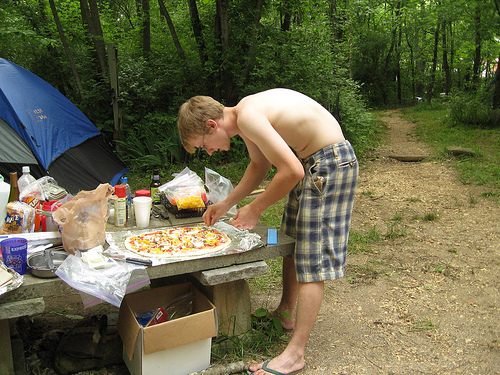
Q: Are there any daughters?
A: No, there are no daughters.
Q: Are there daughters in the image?
A: No, there are no daughters.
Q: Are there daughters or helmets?
A: No, there are no daughters or helmets.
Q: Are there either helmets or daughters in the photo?
A: No, there are no daughters or helmets.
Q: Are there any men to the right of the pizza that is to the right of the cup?
A: Yes, there is a man to the right of the pizza.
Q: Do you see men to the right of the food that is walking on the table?
A: Yes, there is a man to the right of the pizza.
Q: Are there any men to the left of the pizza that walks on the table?
A: No, the man is to the right of the pizza.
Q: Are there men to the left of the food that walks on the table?
A: No, the man is to the right of the pizza.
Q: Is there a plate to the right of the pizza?
A: No, there is a man to the right of the pizza.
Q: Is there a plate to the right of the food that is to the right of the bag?
A: No, there is a man to the right of the pizza.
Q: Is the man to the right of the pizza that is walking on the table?
A: Yes, the man is to the right of the pizza.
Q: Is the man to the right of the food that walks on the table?
A: Yes, the man is to the right of the pizza.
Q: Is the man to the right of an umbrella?
A: No, the man is to the right of the pizza.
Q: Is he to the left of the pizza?
A: No, the man is to the right of the pizza.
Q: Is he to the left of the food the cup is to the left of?
A: No, the man is to the right of the pizza.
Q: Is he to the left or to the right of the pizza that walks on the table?
A: The man is to the right of the pizza.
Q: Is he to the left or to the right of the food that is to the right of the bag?
A: The man is to the right of the pizza.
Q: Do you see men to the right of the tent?
A: Yes, there is a man to the right of the tent.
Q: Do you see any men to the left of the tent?
A: No, the man is to the right of the tent.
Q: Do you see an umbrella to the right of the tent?
A: No, there is a man to the right of the tent.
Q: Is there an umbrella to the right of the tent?
A: No, there is a man to the right of the tent.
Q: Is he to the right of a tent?
A: Yes, the man is to the right of a tent.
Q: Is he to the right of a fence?
A: No, the man is to the right of a tent.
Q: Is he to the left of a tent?
A: No, the man is to the right of a tent.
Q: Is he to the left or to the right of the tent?
A: The man is to the right of the tent.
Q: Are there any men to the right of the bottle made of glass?
A: Yes, there is a man to the right of the bottle.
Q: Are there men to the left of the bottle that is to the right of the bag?
A: No, the man is to the right of the bottle.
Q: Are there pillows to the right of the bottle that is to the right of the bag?
A: No, there is a man to the right of the bottle.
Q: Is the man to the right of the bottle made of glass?
A: Yes, the man is to the right of the bottle.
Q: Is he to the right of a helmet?
A: No, the man is to the right of the bottle.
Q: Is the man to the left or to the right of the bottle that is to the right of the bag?
A: The man is to the right of the bottle.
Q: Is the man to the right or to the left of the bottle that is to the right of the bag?
A: The man is to the right of the bottle.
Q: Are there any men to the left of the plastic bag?
A: No, the man is to the right of the bag.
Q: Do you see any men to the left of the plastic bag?
A: No, the man is to the right of the bag.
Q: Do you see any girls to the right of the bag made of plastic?
A: No, there is a man to the right of the bag.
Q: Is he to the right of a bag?
A: Yes, the man is to the right of a bag.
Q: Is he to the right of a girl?
A: No, the man is to the right of a bag.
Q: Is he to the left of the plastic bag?
A: No, the man is to the right of the bag.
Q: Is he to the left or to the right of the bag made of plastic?
A: The man is to the right of the bag.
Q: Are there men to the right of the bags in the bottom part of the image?
A: Yes, there is a man to the right of the bags.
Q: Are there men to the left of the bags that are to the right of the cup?
A: No, the man is to the right of the bags.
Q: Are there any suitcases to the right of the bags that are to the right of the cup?
A: No, there is a man to the right of the bags.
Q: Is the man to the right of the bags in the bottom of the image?
A: Yes, the man is to the right of the bags.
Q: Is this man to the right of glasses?
A: No, the man is to the right of the bags.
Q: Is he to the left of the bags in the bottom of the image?
A: No, the man is to the right of the bags.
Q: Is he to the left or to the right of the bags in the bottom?
A: The man is to the right of the bags.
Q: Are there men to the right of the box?
A: Yes, there is a man to the right of the box.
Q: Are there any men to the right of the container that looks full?
A: Yes, there is a man to the right of the box.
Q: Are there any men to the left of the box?
A: No, the man is to the right of the box.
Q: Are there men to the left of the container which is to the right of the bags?
A: No, the man is to the right of the box.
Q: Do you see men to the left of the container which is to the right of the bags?
A: No, the man is to the right of the box.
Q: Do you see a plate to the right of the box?
A: No, there is a man to the right of the box.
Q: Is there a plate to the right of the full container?
A: No, there is a man to the right of the box.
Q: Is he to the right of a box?
A: Yes, the man is to the right of a box.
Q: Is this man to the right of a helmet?
A: No, the man is to the right of a box.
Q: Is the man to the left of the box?
A: No, the man is to the right of the box.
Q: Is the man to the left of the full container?
A: No, the man is to the right of the box.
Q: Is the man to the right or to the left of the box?
A: The man is to the right of the box.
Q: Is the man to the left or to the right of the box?
A: The man is to the right of the box.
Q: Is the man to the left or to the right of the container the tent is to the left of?
A: The man is to the right of the box.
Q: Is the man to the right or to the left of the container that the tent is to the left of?
A: The man is to the right of the box.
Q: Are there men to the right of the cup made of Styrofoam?
A: Yes, there is a man to the right of the cup.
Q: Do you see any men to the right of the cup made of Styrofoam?
A: Yes, there is a man to the right of the cup.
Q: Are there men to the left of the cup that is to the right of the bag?
A: No, the man is to the right of the cup.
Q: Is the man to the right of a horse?
A: No, the man is to the right of the cup.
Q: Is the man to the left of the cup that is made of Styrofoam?
A: No, the man is to the right of the cup.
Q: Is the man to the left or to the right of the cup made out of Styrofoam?
A: The man is to the right of the cup.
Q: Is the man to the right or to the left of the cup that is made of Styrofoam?
A: The man is to the right of the cup.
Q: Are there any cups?
A: Yes, there is a cup.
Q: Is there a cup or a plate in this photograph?
A: Yes, there is a cup.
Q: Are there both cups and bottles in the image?
A: Yes, there are both a cup and a bottle.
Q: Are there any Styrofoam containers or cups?
A: Yes, there is a Styrofoam cup.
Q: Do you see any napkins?
A: No, there are no napkins.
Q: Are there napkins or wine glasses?
A: No, there are no napkins or wine glasses.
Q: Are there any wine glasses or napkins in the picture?
A: No, there are no napkins or wine glasses.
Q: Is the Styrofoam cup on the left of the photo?
A: Yes, the cup is on the left of the image.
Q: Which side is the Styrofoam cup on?
A: The cup is on the left of the image.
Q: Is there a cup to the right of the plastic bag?
A: Yes, there is a cup to the right of the bag.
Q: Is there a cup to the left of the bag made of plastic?
A: No, the cup is to the right of the bag.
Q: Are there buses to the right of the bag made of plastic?
A: No, there is a cup to the right of the bag.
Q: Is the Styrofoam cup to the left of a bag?
A: No, the cup is to the right of a bag.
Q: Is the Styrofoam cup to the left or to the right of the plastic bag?
A: The cup is to the right of the bag.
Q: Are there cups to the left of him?
A: Yes, there is a cup to the left of the man.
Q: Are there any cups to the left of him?
A: Yes, there is a cup to the left of the man.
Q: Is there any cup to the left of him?
A: Yes, there is a cup to the left of the man.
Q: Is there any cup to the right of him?
A: No, the cup is to the left of the man.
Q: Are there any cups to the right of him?
A: No, the cup is to the left of the man.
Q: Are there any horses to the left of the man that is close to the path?
A: No, there is a cup to the left of the man.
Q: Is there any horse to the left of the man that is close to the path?
A: No, there is a cup to the left of the man.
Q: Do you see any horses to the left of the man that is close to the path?
A: No, there is a cup to the left of the man.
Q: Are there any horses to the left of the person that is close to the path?
A: No, there is a cup to the left of the man.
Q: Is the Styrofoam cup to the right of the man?
A: No, the cup is to the left of the man.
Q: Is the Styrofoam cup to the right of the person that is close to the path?
A: No, the cup is to the left of the man.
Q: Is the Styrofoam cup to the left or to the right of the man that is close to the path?
A: The cup is to the left of the man.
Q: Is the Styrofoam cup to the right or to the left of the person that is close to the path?
A: The cup is to the left of the man.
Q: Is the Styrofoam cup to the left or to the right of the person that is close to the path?
A: The cup is to the left of the man.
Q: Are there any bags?
A: Yes, there is a bag.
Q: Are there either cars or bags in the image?
A: Yes, there is a bag.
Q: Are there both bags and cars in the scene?
A: No, there is a bag but no cars.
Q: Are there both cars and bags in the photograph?
A: No, there is a bag but no cars.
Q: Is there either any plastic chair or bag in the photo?
A: Yes, there is a plastic bag.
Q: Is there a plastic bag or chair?
A: Yes, there is a plastic bag.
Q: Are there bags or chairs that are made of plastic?
A: Yes, the bag is made of plastic.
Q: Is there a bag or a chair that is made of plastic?
A: Yes, the bag is made of plastic.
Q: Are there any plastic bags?
A: Yes, there is a bag that is made of plastic.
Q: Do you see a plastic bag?
A: Yes, there is a bag that is made of plastic.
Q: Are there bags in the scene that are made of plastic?
A: Yes, there is a bag that is made of plastic.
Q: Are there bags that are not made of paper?
A: Yes, there is a bag that is made of plastic.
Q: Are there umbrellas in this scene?
A: No, there are no umbrellas.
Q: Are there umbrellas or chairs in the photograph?
A: No, there are no umbrellas or chairs.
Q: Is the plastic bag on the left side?
A: Yes, the bag is on the left of the image.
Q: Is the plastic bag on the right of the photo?
A: No, the bag is on the left of the image.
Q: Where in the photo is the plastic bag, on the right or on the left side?
A: The bag is on the left of the image.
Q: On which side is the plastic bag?
A: The bag is on the left of the image.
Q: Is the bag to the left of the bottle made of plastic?
A: Yes, the bag is made of plastic.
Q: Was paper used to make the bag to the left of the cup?
A: No, the bag is made of plastic.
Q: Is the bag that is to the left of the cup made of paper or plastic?
A: The bag is made of plastic.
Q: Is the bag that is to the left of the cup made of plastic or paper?
A: The bag is made of plastic.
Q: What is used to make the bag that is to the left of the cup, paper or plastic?
A: The bag is made of plastic.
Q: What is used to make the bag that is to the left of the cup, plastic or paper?
A: The bag is made of plastic.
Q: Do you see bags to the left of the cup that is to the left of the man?
A: Yes, there is a bag to the left of the cup.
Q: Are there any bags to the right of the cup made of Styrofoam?
A: No, the bag is to the left of the cup.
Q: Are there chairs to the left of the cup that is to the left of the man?
A: No, there is a bag to the left of the cup.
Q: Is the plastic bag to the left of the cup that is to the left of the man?
A: Yes, the bag is to the left of the cup.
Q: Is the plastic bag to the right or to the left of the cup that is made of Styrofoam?
A: The bag is to the left of the cup.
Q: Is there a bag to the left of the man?
A: Yes, there is a bag to the left of the man.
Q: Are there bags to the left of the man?
A: Yes, there is a bag to the left of the man.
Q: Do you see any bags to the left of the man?
A: Yes, there is a bag to the left of the man.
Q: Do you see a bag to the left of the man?
A: Yes, there is a bag to the left of the man.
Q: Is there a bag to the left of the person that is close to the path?
A: Yes, there is a bag to the left of the man.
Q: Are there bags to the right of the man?
A: No, the bag is to the left of the man.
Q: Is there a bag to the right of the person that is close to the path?
A: No, the bag is to the left of the man.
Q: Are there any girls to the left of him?
A: No, there is a bag to the left of the man.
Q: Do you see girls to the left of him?
A: No, there is a bag to the left of the man.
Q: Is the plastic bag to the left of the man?
A: Yes, the bag is to the left of the man.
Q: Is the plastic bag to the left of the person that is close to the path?
A: Yes, the bag is to the left of the man.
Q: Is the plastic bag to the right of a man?
A: No, the bag is to the left of a man.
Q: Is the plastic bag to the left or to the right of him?
A: The bag is to the left of the man.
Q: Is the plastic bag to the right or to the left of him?
A: The bag is to the left of the man.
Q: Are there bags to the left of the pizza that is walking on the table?
A: Yes, there is a bag to the left of the pizza.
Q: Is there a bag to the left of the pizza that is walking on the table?
A: Yes, there is a bag to the left of the pizza.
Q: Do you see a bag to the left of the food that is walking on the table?
A: Yes, there is a bag to the left of the pizza.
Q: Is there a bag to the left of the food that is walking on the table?
A: Yes, there is a bag to the left of the pizza.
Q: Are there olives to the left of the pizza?
A: No, there is a bag to the left of the pizza.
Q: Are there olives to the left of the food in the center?
A: No, there is a bag to the left of the pizza.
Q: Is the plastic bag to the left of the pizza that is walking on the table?
A: Yes, the bag is to the left of the pizza.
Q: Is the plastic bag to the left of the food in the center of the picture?
A: Yes, the bag is to the left of the pizza.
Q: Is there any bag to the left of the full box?
A: Yes, there is a bag to the left of the box.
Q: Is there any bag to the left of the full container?
A: Yes, there is a bag to the left of the box.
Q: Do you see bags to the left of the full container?
A: Yes, there is a bag to the left of the box.